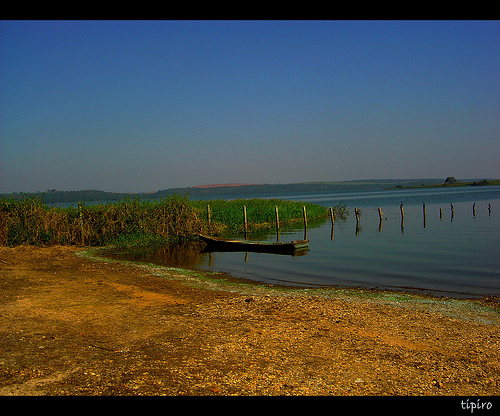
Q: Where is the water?
A: By the shore.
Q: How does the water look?
A: Calm.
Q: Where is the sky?
A: Above the shore.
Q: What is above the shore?
A: The sky.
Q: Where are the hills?
A: In the distance.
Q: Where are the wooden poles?
A: In the water.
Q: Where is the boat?
A: In the water.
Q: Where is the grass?
A: On the shore.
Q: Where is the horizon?
A: In the distance.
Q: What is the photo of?
A: A body of water.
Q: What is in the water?
A: Wooden posts.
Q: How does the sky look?
A: Clear and blue.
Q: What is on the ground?
A: Mud.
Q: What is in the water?
A: Ripples.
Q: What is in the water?
A: A boat.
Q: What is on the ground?
A: Rocks.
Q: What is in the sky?
A: The sky is clear.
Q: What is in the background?
A: Mountain.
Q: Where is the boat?
A: In the water.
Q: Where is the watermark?
A: Bottom right.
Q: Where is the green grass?
A: Middle left of the photo.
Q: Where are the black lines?
A: Top and bottom of the image.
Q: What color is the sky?
A: Blue.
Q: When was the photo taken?
A: Daytime.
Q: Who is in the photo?
A: Nobody.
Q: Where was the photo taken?
A: By a lake.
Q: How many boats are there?
A: One.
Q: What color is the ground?
A: Brown.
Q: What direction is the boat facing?
A: Left.